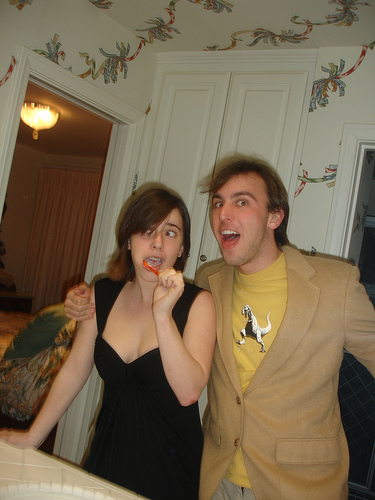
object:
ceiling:
[16, 79, 113, 155]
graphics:
[31, 32, 73, 73]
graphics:
[204, 0, 366, 51]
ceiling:
[88, 0, 374, 50]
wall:
[0, 0, 158, 465]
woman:
[0, 178, 216, 497]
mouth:
[141, 255, 165, 269]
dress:
[82, 275, 219, 499]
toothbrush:
[142, 261, 160, 282]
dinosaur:
[237, 303, 272, 351]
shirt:
[224, 251, 290, 489]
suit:
[188, 241, 374, 499]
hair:
[196, 152, 290, 246]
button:
[233, 438, 240, 447]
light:
[21, 98, 59, 128]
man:
[63, 154, 375, 499]